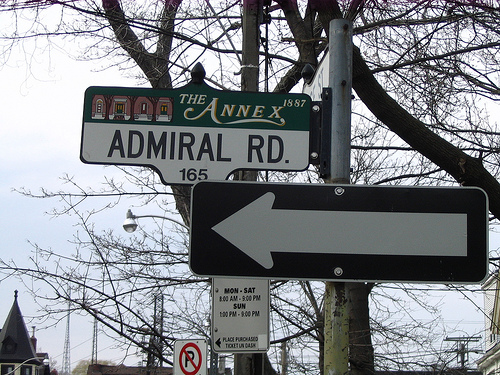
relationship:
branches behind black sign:
[0, 0, 499, 372] [185, 178, 491, 283]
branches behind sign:
[0, 0, 499, 370] [210, 274, 271, 355]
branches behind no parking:
[0, 0, 499, 370] [171, 339, 208, 374]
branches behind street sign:
[0, 0, 499, 370] [79, 84, 313, 186]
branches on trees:
[0, 0, 499, 372] [3, 0, 499, 370]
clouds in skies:
[0, 0, 499, 371] [0, 0, 499, 371]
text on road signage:
[108, 92, 306, 179] [77, 84, 312, 186]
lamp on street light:
[123, 207, 139, 231] [124, 210, 226, 373]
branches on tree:
[0, 0, 499, 372] [2, 0, 498, 371]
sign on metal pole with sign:
[212, 274, 270, 354] [239, 11, 261, 90]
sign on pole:
[212, 274, 270, 354] [235, 0, 270, 372]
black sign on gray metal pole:
[185, 178, 491, 283] [326, 17, 353, 185]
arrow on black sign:
[211, 191, 467, 269] [185, 178, 491, 283]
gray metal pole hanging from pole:
[326, 17, 353, 185] [229, 14, 294, 341]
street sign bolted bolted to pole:
[322, 176, 361, 284] [324, 20, 360, 370]